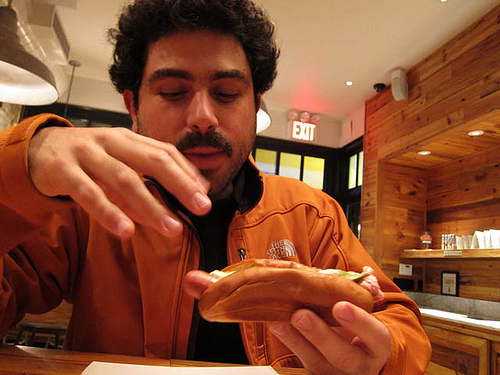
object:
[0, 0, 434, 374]
man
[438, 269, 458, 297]
frame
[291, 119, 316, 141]
sign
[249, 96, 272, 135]
light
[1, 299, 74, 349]
stool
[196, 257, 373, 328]
bun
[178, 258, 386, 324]
dog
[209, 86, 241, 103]
eye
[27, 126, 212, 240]
hand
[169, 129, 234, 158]
mustached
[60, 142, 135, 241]
finger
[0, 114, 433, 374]
jacket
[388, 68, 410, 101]
speaker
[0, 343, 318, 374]
table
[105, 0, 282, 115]
hair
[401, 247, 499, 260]
shelf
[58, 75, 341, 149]
wall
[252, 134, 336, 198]
window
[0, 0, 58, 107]
lamp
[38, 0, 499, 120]
ceiling